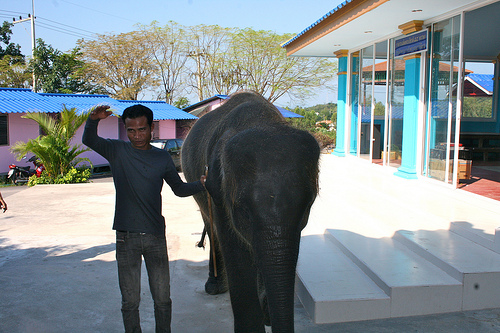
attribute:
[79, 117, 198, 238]
shirt — blue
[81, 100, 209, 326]
man — dark, grey, black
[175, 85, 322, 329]
elephant — small, gray, African, grey, black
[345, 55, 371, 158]
window — glass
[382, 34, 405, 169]
window — glass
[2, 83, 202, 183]
building — pink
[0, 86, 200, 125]
roof — blue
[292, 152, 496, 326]
stairs — white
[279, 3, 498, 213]
building — blue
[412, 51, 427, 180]
trim — white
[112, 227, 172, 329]
jeans — blue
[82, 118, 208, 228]
shirt — blue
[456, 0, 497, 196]
door — open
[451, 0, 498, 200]
door — open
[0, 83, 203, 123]
roof — blue, metal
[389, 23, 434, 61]
sign — blue, white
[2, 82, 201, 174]
building — pink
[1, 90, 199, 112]
roof — blue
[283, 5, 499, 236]
building — blue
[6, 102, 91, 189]
bush — large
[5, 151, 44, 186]
moped — parked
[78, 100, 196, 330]
man — short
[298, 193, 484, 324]
stairs — a white set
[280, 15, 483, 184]
building — light blue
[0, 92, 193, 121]
awning —  blue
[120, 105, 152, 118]
hair — black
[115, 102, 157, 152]
head — mans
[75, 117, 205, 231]
shirt — blue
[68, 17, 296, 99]
trees — in the distance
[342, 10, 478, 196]
front — glass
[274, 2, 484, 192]
building — business